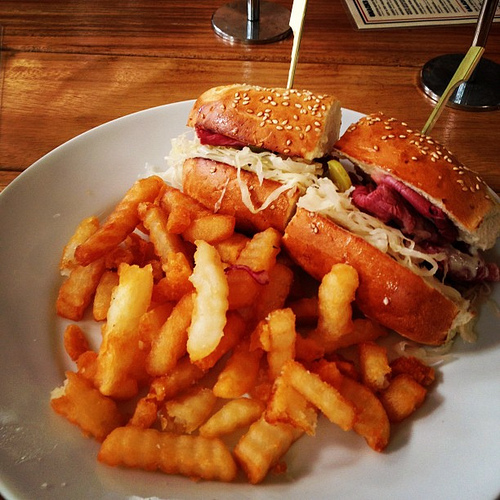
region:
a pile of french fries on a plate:
[70, 184, 348, 481]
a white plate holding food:
[2, 66, 492, 498]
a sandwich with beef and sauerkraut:
[181, 70, 496, 332]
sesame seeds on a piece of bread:
[246, 86, 311, 132]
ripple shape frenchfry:
[123, 423, 214, 469]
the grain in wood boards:
[40, 28, 142, 95]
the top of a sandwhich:
[195, 75, 333, 156]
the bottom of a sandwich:
[168, 146, 293, 233]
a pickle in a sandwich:
[324, 154, 363, 196]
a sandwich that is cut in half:
[186, 70, 490, 365]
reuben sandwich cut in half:
[182, 86, 497, 341]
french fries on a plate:
[50, 180, 434, 480]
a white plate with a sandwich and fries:
[9, 100, 495, 498]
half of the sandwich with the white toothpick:
[181, 83, 333, 232]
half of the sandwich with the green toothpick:
[289, 116, 496, 351]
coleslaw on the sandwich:
[171, 144, 480, 343]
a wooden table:
[2, 3, 494, 182]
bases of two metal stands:
[215, 5, 497, 111]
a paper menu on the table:
[348, 0, 497, 27]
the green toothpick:
[426, 44, 480, 142]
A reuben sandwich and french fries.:
[0, 83, 499, 499]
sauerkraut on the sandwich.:
[140, 127, 445, 272]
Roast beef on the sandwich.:
[190, 130, 497, 301]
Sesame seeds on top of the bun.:
[187, 83, 497, 203]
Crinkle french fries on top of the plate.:
[51, 175, 442, 480]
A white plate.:
[1, 100, 499, 499]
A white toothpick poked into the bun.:
[280, 0, 312, 92]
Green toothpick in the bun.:
[405, 45, 485, 139]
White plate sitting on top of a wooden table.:
[1, 0, 499, 496]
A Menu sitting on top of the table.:
[341, 2, 491, 29]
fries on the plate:
[37, 173, 435, 485]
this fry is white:
[183, 243, 230, 365]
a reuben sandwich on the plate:
[185, 72, 486, 349]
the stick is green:
[415, 44, 483, 137]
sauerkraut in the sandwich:
[172, 132, 313, 197]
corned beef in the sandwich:
[356, 170, 474, 272]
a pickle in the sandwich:
[322, 154, 352, 194]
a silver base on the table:
[203, 2, 295, 44]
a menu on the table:
[335, 0, 494, 36]